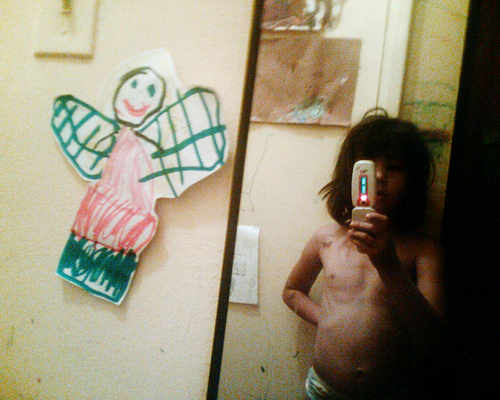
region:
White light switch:
[26, 2, 103, 57]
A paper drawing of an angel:
[45, 60, 221, 301]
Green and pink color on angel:
[43, 70, 225, 307]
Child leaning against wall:
[272, 100, 459, 395]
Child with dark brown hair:
[275, 105, 457, 396]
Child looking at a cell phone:
[276, 118, 447, 394]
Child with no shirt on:
[272, 105, 462, 395]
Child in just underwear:
[296, 365, 408, 398]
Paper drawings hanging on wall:
[245, 0, 356, 125]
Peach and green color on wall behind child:
[406, 0, 463, 228]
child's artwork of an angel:
[48, 46, 229, 306]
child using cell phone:
[280, 106, 445, 398]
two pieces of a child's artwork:
[248, 0, 363, 127]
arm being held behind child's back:
[280, 221, 339, 324]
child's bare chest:
[313, 223, 408, 338]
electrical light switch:
[31, 1, 96, 61]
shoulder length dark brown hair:
[318, 106, 434, 235]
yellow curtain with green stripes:
[397, 1, 467, 231]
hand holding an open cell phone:
[345, 158, 397, 258]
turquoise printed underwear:
[303, 363, 333, 398]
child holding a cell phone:
[317, 111, 433, 276]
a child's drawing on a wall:
[44, 46, 234, 298]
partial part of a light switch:
[27, 1, 99, 70]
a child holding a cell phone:
[279, 116, 446, 392]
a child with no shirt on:
[278, 119, 458, 397]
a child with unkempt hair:
[320, 114, 432, 246]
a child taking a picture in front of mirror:
[195, 1, 489, 399]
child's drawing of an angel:
[40, 59, 232, 310]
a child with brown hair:
[321, 116, 441, 238]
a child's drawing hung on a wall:
[236, 26, 368, 130]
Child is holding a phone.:
[361, 156, 379, 255]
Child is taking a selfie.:
[292, 107, 448, 398]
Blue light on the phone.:
[355, 167, 368, 208]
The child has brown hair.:
[321, 108, 439, 243]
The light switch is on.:
[23, 0, 105, 62]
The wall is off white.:
[37, 305, 202, 395]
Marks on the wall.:
[233, 347, 280, 397]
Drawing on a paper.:
[48, 57, 230, 317]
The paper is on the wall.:
[36, 55, 235, 325]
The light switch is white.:
[35, 10, 97, 57]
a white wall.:
[12, 299, 67, 372]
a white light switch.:
[34, 0, 98, 67]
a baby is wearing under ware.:
[301, 367, 352, 398]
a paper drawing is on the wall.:
[34, 49, 238, 307]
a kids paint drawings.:
[235, 4, 360, 143]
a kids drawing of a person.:
[38, 48, 241, 305]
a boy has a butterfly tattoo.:
[311, 237, 342, 252]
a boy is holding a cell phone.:
[337, 156, 390, 235]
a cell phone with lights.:
[351, 160, 374, 207]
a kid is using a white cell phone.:
[289, 107, 492, 385]